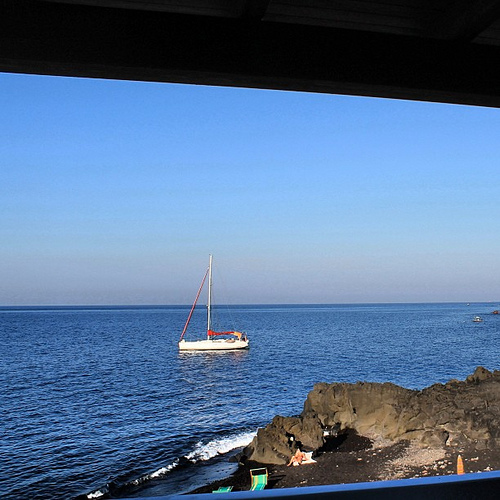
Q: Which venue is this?
A: This is an ocean.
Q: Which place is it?
A: It is an ocean.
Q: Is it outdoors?
A: Yes, it is outdoors.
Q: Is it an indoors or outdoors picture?
A: It is outdoors.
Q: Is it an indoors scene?
A: No, it is outdoors.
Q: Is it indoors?
A: No, it is outdoors.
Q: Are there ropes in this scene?
A: No, there are no ropes.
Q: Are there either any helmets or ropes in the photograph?
A: No, there are no ropes or helmets.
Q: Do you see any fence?
A: No, there are no fences.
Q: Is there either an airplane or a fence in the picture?
A: No, there are no fences or airplanes.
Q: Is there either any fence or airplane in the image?
A: No, there are no fences or airplanes.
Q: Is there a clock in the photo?
A: No, there are no clocks.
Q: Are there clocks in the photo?
A: No, there are no clocks.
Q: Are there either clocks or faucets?
A: No, there are no clocks or faucets.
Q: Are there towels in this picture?
A: Yes, there is a towel.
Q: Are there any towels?
A: Yes, there is a towel.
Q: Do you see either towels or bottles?
A: Yes, there is a towel.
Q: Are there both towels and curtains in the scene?
A: No, there is a towel but no curtains.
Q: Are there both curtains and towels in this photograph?
A: No, there is a towel but no curtains.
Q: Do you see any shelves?
A: No, there are no shelves.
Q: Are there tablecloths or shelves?
A: No, there are no shelves or tablecloths.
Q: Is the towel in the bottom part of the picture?
A: Yes, the towel is in the bottom of the image.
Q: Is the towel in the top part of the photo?
A: No, the towel is in the bottom of the image.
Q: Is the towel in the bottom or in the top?
A: The towel is in the bottom of the image.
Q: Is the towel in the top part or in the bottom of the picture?
A: The towel is in the bottom of the image.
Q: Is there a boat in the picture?
A: Yes, there is a boat.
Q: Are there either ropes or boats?
A: Yes, there is a boat.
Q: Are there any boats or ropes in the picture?
A: Yes, there is a boat.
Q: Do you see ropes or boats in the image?
A: Yes, there is a boat.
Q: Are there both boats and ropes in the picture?
A: No, there is a boat but no ropes.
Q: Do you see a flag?
A: No, there are no flags.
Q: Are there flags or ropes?
A: No, there are no flags or ropes.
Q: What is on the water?
A: The boat is on the water.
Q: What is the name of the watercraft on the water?
A: The watercraft is a boat.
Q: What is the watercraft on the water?
A: The watercraft is a boat.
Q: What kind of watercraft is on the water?
A: The watercraft is a boat.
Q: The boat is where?
A: The boat is on the water.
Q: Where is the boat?
A: The boat is on the water.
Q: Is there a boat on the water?
A: Yes, there is a boat on the water.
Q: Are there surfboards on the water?
A: No, there is a boat on the water.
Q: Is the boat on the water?
A: Yes, the boat is on the water.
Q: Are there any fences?
A: No, there are no fences.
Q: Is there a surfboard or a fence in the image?
A: No, there are no fences or surfboards.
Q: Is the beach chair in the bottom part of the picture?
A: Yes, the beach chair is in the bottom of the image.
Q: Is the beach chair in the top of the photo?
A: No, the beach chair is in the bottom of the image.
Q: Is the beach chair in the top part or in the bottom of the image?
A: The beach chair is in the bottom of the image.